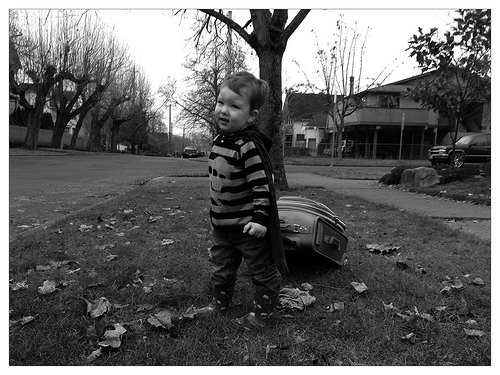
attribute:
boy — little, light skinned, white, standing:
[193, 72, 290, 325]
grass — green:
[10, 186, 489, 365]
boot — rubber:
[195, 282, 234, 321]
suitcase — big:
[275, 197, 349, 270]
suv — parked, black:
[428, 135, 491, 171]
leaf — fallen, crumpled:
[98, 324, 129, 349]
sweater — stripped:
[211, 131, 270, 228]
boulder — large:
[401, 167, 439, 192]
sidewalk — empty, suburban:
[284, 172, 493, 239]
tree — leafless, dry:
[9, 10, 97, 148]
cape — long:
[226, 125, 288, 278]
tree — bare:
[177, 8, 310, 189]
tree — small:
[403, 9, 492, 171]